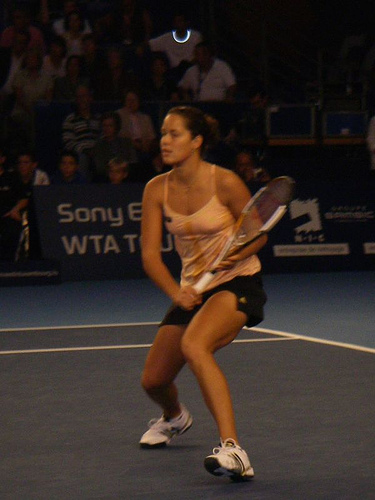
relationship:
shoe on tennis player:
[141, 401, 187, 447] [145, 203, 248, 494]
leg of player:
[181, 288, 255, 483] [139, 104, 270, 481]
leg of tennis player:
[136, 311, 183, 439] [137, 181, 252, 422]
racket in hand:
[192, 174, 296, 294] [176, 285, 203, 306]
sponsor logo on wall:
[261, 183, 348, 274] [341, 167, 360, 265]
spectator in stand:
[15, 108, 145, 204] [29, 114, 138, 289]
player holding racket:
[139, 104, 270, 481] [183, 183, 294, 288]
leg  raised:
[192, 421, 262, 491] [206, 455, 240, 500]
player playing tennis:
[139, 104, 270, 481] [177, 194, 276, 307]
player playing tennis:
[139, 104, 270, 481] [186, 176, 290, 288]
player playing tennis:
[139, 104, 270, 481] [179, 182, 304, 299]